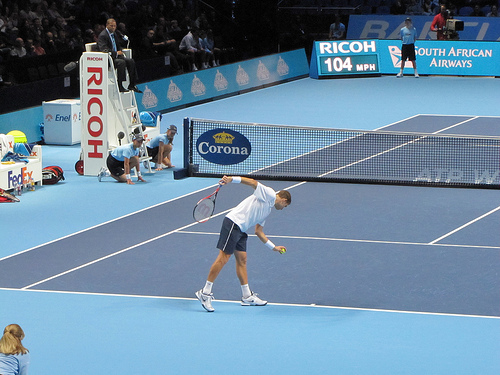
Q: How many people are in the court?
A: Five.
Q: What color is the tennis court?
A: Blue.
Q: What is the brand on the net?
A: Corona.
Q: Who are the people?
A: Men.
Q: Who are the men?
A: Tennis players.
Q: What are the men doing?
A: Playing tennis.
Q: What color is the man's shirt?
A: White.